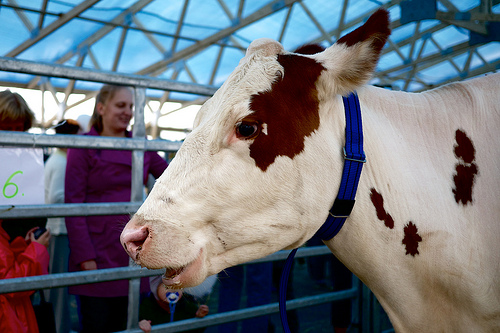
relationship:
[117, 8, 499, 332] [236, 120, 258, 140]
cow has eye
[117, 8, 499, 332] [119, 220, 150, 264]
cow has nose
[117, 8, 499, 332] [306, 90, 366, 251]
cow has collar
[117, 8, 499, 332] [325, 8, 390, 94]
cow has ear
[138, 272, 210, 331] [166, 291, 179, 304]
baby has pacifier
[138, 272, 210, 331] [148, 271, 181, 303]
baby has hat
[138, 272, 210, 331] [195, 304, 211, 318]
baby has hand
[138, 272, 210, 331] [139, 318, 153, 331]
baby has hand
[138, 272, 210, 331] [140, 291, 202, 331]
baby wearing jacket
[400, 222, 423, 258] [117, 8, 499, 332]
spot on cow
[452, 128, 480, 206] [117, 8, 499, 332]
spots on cow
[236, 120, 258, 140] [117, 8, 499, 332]
eye on cow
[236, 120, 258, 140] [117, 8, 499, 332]
eye of cow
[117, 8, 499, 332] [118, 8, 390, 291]
cow has head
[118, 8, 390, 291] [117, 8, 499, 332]
head of cow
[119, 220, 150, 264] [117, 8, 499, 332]
nose of cow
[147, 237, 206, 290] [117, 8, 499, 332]
mouth of cow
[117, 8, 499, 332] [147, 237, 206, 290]
cow has mouth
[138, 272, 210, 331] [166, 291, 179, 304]
baby with pacifier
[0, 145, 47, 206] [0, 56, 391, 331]
sign on gate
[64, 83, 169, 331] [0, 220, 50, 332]
woman has coat